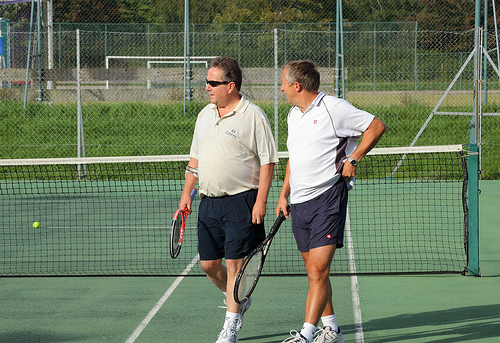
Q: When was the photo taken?
A: Daytime.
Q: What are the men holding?
A: Tennis rackets.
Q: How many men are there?
A: Two.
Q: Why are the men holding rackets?
A: They were playing tennis.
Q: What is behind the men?
A: A tennis net.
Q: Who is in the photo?
A: Two men.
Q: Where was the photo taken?
A: A tennis court.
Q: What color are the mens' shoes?
A: White.